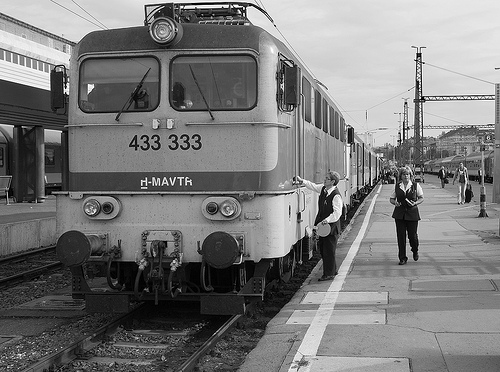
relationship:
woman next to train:
[295, 165, 347, 283] [50, 0, 395, 314]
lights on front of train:
[216, 200, 243, 220] [50, 0, 395, 314]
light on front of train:
[79, 195, 100, 218] [50, 0, 395, 314]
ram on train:
[194, 225, 249, 277] [50, 0, 395, 314]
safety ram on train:
[54, 228, 101, 268] [50, 0, 395, 314]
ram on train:
[194, 230, 244, 268] [50, 0, 395, 314]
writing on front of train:
[139, 170, 193, 193] [64, 33, 346, 277]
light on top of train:
[148, 17, 182, 44] [50, 0, 395, 314]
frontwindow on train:
[168, 56, 255, 111] [50, 0, 395, 314]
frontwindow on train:
[76, 58, 160, 112] [50, 0, 395, 314]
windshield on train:
[79, 55, 161, 110] [70, 24, 393, 294]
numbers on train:
[127, 133, 203, 151] [87, 22, 314, 273]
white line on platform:
[286, 179, 399, 369] [283, 178, 499, 370]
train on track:
[50, 0, 395, 314] [53, 304, 240, 369]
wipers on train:
[108, 63, 219, 122] [50, 0, 395, 314]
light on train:
[148, 17, 184, 42] [66, 25, 306, 307]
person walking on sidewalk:
[390, 166, 425, 269] [371, 198, 431, 370]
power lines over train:
[357, 83, 415, 135] [50, 0, 395, 314]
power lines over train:
[421, 54, 498, 87] [50, 0, 395, 314]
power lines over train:
[418, 107, 474, 127] [50, 0, 395, 314]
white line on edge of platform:
[286, 183, 388, 369] [236, 176, 498, 370]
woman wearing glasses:
[292, 170, 348, 283] [324, 175, 332, 180]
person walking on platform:
[453, 160, 470, 210] [236, 176, 498, 370]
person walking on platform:
[436, 165, 446, 187] [236, 176, 498, 370]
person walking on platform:
[390, 166, 422, 263] [236, 176, 498, 370]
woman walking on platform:
[292, 170, 348, 283] [236, 176, 498, 370]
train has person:
[90, 30, 421, 288] [390, 166, 425, 269]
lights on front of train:
[199, 193, 246, 224] [59, 10, 380, 287]